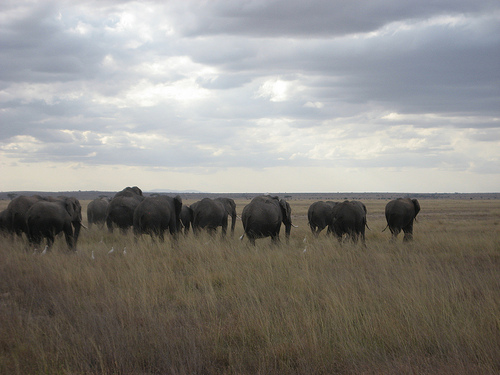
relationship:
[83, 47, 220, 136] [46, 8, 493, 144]
clouds in sky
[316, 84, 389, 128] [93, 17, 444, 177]
clouds in sky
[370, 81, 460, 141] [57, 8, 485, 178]
clouds in sky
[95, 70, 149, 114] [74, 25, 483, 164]
clouds in sky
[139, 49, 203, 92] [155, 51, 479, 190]
clouds in sky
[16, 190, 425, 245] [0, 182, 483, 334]
cows in field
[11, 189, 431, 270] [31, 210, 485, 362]
elephants in grass field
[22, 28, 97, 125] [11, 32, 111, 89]
clouds in sky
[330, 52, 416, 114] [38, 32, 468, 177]
clouds in sky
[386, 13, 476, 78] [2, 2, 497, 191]
clouds in sky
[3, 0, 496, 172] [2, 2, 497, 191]
clouds in sky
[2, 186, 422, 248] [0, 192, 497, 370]
cows in field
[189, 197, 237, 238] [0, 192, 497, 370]
elephants walking in field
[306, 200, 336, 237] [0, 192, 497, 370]
elephants walking in field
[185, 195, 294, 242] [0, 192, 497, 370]
elephants walking in field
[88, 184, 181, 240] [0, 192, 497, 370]
elephants walking in field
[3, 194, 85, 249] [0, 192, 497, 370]
elephants walking in field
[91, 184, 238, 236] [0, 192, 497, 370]
elephants walking in field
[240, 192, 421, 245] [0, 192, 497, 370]
elephants walking in field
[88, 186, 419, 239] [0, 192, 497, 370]
elephants walking in field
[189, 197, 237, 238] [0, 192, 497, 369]
elephants walking in grass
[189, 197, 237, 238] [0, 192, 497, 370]
elephants walking to other side of field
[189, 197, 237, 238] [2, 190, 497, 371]
elephants walking in wildlife park